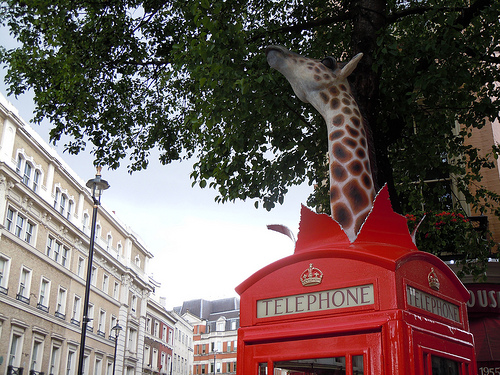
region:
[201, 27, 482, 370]
a giraffe is eating leaves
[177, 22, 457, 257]
giraffe can reach the canopy of tree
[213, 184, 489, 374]
cabin of public phone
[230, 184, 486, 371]
london cabins of phone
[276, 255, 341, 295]
a crown on top of cabin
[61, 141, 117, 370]
light pole on the street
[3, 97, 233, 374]
buildings of a city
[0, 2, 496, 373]
picture of a giraffe in a city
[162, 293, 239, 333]
roof of building is black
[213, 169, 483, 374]
phone cabin is broken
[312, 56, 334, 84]
Giraffe has large eye.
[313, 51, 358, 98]
Giraffe has dark eye.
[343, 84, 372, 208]
Giraffe has black and brown spots.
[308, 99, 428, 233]
Giraffe has long neck.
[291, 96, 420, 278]
Giraffe's head is poking thru the top of booth.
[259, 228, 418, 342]
Red telephone booth on side of road.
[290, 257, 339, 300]
Gold crown on telephone booth.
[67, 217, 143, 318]
Large black light pole.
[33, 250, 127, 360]
Many windows on side of building.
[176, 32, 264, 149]
Green leaves on tree.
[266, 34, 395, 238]
a giraffe head bursting through a telephone booth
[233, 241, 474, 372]
a red telephone booth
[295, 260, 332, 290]
a crown on a telephone booth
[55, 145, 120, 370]
a tall light pole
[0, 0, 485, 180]
a green leafy tree branch hanging over a telephone booth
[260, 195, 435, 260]
the ripped top of a telephone booth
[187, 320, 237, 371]
a red brick building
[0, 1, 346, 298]
a pale blue sky overhead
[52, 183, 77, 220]
a trio of arched windows on a building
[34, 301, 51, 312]
a railing around a window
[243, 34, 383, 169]
giraffe is feeding on tree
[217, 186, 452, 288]
telephone booth is ripped open at top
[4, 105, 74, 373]
beige and white building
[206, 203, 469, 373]
red telephone booth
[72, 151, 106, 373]
tall black pole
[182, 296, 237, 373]
red and white building with black rooftop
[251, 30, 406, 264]
giraffe's head piercing through telephone booth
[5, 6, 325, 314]
picture taken in broad daylight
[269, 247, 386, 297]
golden crown on telephone booth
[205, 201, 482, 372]
telephone booth in the street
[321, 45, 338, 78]
Giraffe has dark eye.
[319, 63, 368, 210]
Giraffe has black and brown spots.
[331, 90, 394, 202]
Giraffe has long neck.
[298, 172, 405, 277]
Giraffe's head has poked thru the top of telephone booth.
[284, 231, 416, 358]
Red telephone booth on street.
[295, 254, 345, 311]
Crown on top of telephone booth.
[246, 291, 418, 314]
Telephone written on side of booth.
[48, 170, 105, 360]
Tall black light post near building.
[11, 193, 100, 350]
Many windows on building.